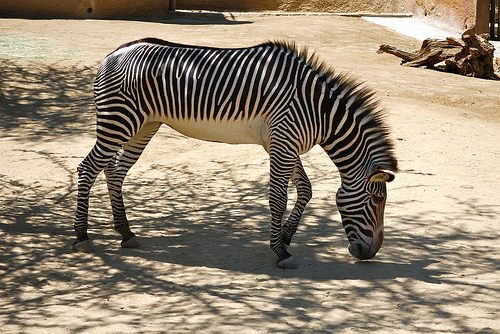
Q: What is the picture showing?
A: A zebra.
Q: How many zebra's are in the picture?
A: One.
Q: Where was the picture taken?
A: Wildlife park.